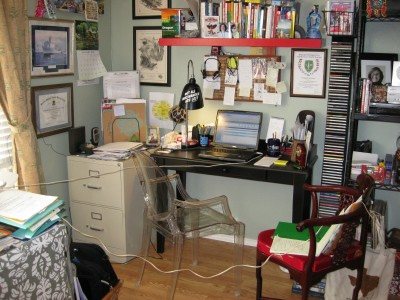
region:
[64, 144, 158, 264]
beige two-drawer file cabinet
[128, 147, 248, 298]
see-trough plastic desk chair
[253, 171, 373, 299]
chair covered with notebooks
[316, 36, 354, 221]
compact discs stacked in a column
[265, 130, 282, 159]
black cup holding two pencils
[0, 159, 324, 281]
two wires strung across the room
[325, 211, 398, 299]
white carrying bag with state of Texas emblam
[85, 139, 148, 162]
pile of notebooks and papers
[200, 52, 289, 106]
bulletin board filled with notes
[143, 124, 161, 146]
framed photograph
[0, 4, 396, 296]
A work space.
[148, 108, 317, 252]
Laptop on top of a black desk.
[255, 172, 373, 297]
Brown wooden chair.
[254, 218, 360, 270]
Red seat on the chair.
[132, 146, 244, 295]
Clear plastic chair.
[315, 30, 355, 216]
A rack filled with CD cases.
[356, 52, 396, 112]
Picture of a woman in a black frame.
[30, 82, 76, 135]
Framed diploma hanging on a wall.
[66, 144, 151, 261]
White file cabinet.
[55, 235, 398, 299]
Brown hardwood floor.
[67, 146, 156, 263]
a beige colored 2 drawer filing cabinet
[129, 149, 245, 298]
a clear plastic desk chair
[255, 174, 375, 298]
a dark brown wooden chair with red cushion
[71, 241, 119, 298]
a black backpack on the floor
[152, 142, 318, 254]
a black office desk with drawer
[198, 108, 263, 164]
a laptop computer on the desk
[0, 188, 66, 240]
a stack of white and blue folders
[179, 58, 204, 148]
a black lamp on the desk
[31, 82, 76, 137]
a framed diploma on the wall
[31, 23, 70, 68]
a framed picture on the wall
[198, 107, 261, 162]
Open silver laptop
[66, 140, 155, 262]
White two drawer filing cabinet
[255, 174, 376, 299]
Dark wood chair with red cushion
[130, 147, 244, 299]
Clear plastic chair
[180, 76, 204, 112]
Black desk lamp shade with white letters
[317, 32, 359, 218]
Tall black CD organizer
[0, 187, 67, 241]
Stack of white paper and blue folders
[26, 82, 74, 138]
Certificate in a wood picture frame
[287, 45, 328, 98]
Paper in a wood frame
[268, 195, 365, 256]
Green and white papers on a chair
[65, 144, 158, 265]
a white filing cabinet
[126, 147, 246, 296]
a clear plastic chair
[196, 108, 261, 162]
an open laptop computer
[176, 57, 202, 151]
a black desk lamp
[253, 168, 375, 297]
a padded wooden chair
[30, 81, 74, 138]
a framed certificate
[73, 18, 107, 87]
a hanging wall calendar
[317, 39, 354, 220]
a stack of CDs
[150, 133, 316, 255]
a small black desk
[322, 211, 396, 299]
a beige bag with image of Texas